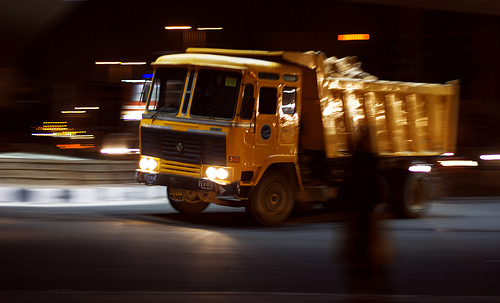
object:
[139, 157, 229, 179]
four lights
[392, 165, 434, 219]
rear tire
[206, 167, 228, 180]
headlight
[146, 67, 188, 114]
window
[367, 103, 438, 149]
wall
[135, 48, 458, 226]
bus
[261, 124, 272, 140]
decal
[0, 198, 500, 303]
pavement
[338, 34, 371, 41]
orange light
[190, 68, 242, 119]
window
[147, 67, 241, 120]
windshield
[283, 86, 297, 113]
window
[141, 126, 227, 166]
grill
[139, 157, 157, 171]
light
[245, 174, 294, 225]
tire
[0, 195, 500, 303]
street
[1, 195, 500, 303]
road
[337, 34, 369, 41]
light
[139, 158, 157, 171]
headlight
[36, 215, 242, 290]
reflection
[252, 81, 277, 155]
door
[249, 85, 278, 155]
arm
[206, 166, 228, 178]
light